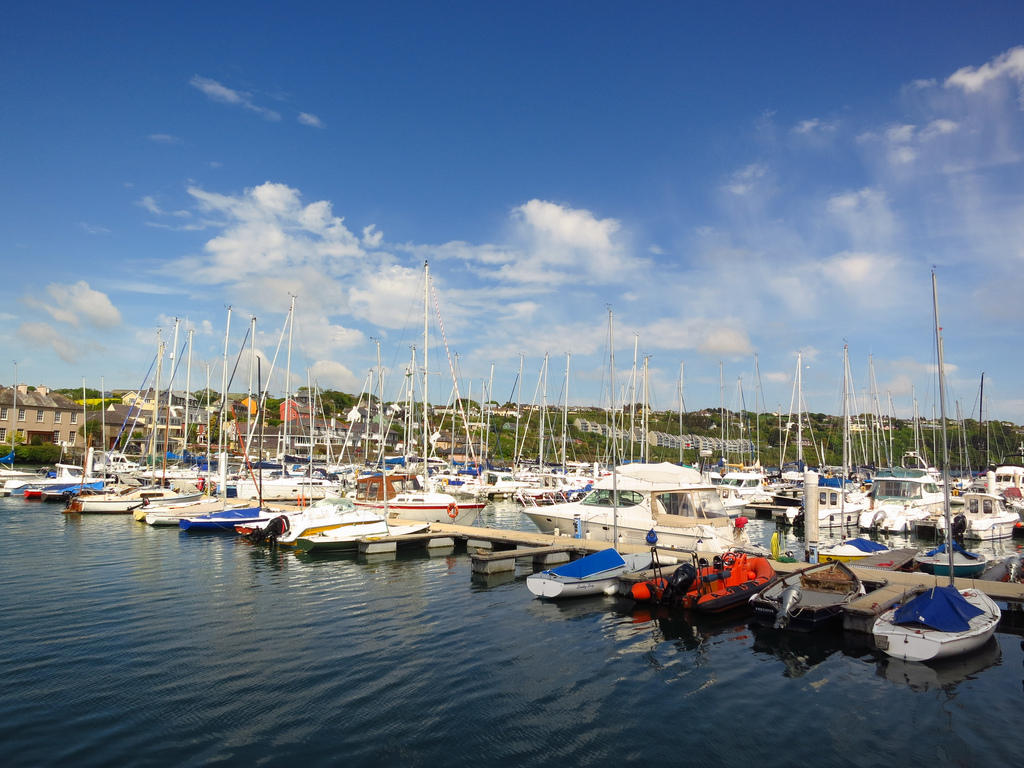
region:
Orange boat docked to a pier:
[624, 548, 768, 625]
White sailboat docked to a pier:
[872, 241, 1003, 671]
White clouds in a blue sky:
[172, 164, 757, 364]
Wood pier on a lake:
[331, 516, 1021, 612]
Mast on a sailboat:
[924, 263, 972, 593]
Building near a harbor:
[3, 383, 92, 451]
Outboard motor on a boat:
[258, 509, 294, 548]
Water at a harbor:
[3, 499, 1021, 765]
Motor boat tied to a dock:
[521, 461, 759, 544]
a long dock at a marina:
[204, 495, 1021, 613]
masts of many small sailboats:
[93, 268, 1020, 585]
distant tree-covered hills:
[67, 385, 1017, 466]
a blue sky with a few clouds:
[0, 3, 1021, 424]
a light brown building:
[0, 383, 87, 447]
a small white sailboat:
[867, 584, 1000, 664]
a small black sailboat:
[735, 559, 863, 643]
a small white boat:
[517, 547, 655, 599]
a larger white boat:
[519, 462, 735, 551]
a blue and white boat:
[867, 572, 1003, 678]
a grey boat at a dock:
[724, 554, 857, 649]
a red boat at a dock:
[605, 539, 777, 637]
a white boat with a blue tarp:
[534, 529, 667, 618]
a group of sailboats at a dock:
[42, 307, 981, 704]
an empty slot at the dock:
[404, 523, 509, 597]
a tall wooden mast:
[383, 251, 445, 501]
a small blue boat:
[169, 494, 268, 539]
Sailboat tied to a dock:
[866, 259, 1004, 675]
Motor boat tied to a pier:
[517, 458, 767, 556]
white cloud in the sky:
[521, 194, 648, 281]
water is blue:
[290, 656, 426, 740]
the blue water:
[351, 604, 475, 728]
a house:
[7, 380, 87, 447]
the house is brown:
[9, 390, 90, 438]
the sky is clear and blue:
[372, 149, 475, 214]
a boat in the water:
[889, 556, 1023, 731]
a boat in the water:
[778, 563, 833, 672]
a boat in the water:
[630, 551, 716, 618]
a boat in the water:
[564, 535, 622, 611]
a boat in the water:
[318, 429, 388, 556]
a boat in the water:
[242, 492, 332, 553]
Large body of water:
[103, 617, 304, 726]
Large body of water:
[78, 581, 271, 677]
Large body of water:
[174, 663, 374, 765]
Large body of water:
[119, 601, 336, 754]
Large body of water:
[161, 625, 365, 758]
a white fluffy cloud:
[546, 221, 589, 272]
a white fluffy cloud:
[637, 291, 774, 408]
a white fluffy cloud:
[501, 294, 550, 356]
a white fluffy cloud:
[296, 325, 377, 377]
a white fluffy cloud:
[375, 265, 445, 348]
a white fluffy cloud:
[204, 168, 353, 298]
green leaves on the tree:
[795, 408, 841, 443]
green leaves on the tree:
[471, 429, 547, 455]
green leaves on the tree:
[550, 364, 611, 466]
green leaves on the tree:
[801, 411, 865, 466]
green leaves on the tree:
[915, 414, 929, 452]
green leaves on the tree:
[400, 367, 473, 437]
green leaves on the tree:
[637, 405, 742, 460]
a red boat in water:
[643, 551, 765, 644]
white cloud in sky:
[497, 171, 647, 301]